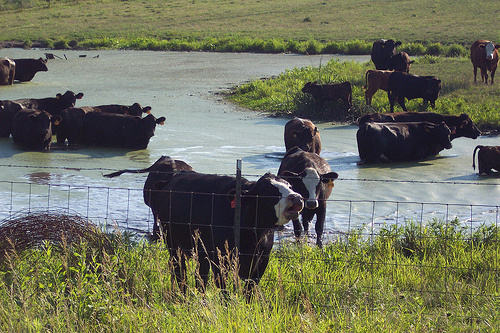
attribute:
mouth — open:
[283, 192, 299, 223]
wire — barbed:
[282, 185, 489, 316]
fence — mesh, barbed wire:
[6, 164, 494, 323]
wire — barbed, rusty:
[13, 177, 486, 330]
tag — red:
[228, 196, 239, 212]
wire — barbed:
[330, 154, 497, 209]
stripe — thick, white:
[299, 159, 324, 201]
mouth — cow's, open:
[282, 201, 302, 218]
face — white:
[270, 177, 304, 227]